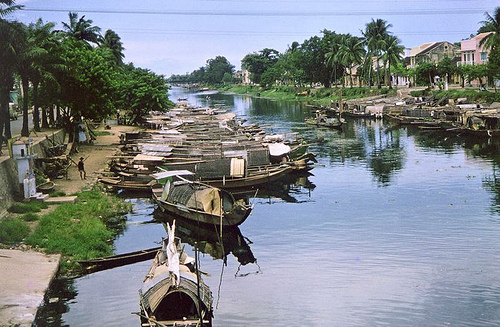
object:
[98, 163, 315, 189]
boat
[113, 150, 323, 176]
boat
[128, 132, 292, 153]
boat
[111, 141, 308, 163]
boat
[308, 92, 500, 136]
boats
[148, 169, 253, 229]
boats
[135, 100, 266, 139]
boats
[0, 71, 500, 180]
ground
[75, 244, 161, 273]
canoe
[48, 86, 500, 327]
water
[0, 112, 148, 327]
river bank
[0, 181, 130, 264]
greens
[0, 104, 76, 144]
trunk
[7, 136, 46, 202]
ojects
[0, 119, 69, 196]
wall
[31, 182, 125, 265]
tie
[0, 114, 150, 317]
dock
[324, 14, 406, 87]
palm trees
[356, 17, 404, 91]
tree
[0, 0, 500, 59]
sky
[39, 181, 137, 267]
grass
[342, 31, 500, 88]
houses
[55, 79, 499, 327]
water canal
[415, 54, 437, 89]
tree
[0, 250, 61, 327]
cement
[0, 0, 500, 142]
foreground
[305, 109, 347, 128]
boat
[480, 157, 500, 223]
reflection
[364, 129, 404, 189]
reflection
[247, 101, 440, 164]
reflection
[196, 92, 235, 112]
reflection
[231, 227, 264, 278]
reflection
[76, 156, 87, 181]
man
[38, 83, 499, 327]
river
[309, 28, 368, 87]
leaves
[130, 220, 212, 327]
boat